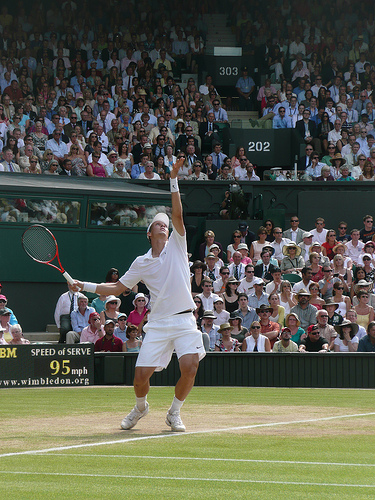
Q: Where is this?
A: This is at the stadium.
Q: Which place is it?
A: It is a stadium.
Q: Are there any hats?
A: Yes, there is a hat.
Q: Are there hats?
A: Yes, there is a hat.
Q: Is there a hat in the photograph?
A: Yes, there is a hat.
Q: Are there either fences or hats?
A: Yes, there is a hat.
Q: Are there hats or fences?
A: Yes, there is a hat.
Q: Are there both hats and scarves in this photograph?
A: No, there is a hat but no scarves.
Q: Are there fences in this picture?
A: No, there are no fences.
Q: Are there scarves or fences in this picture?
A: No, there are no fences or scarves.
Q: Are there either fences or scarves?
A: No, there are no fences or scarves.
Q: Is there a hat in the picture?
A: Yes, there is a hat.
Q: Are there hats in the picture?
A: Yes, there is a hat.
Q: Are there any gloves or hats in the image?
A: Yes, there is a hat.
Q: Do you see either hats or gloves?
A: Yes, there is a hat.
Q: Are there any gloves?
A: No, there are no gloves.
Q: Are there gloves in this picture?
A: No, there are no gloves.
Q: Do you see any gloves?
A: No, there are no gloves.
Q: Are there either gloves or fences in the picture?
A: No, there are no gloves or fences.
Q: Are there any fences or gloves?
A: No, there are no gloves or fences.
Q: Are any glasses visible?
A: No, there are no glasses.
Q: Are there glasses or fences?
A: No, there are no glasses or fences.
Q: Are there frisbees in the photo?
A: No, there are no frisbees.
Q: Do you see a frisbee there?
A: No, there are no frisbees.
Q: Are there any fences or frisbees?
A: No, there are no frisbees or fences.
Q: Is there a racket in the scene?
A: Yes, there is a racket.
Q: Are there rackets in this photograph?
A: Yes, there is a racket.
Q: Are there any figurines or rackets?
A: Yes, there is a racket.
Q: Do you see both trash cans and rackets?
A: No, there is a racket but no trash cans.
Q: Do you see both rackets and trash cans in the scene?
A: No, there is a racket but no trash cans.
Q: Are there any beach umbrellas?
A: No, there are no beach umbrellas.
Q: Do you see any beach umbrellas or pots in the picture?
A: No, there are no beach umbrellas or pots.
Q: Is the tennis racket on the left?
A: Yes, the tennis racket is on the left of the image.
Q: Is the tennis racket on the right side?
A: No, the tennis racket is on the left of the image.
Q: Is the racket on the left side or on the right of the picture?
A: The racket is on the left of the image.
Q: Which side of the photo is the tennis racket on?
A: The tennis racket is on the left of the image.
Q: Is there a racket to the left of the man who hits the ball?
A: Yes, there is a racket to the left of the man.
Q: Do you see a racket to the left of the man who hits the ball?
A: Yes, there is a racket to the left of the man.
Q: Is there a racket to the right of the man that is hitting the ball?
A: No, the racket is to the left of the man.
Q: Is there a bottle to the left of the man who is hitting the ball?
A: No, there is a racket to the left of the man.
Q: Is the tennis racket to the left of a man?
A: Yes, the tennis racket is to the left of a man.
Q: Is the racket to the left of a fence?
A: No, the racket is to the left of a man.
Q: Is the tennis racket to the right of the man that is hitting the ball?
A: No, the tennis racket is to the left of the man.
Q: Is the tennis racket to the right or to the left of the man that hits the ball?
A: The tennis racket is to the left of the man.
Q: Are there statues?
A: No, there are no statues.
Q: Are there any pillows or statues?
A: No, there are no statues or pillows.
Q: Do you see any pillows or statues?
A: No, there are no statues or pillows.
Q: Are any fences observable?
A: No, there are no fences.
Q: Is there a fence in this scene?
A: No, there are no fences.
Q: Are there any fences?
A: No, there are no fences.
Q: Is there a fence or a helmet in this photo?
A: No, there are no fences or helmets.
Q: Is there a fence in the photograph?
A: No, there are no fences.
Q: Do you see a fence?
A: No, there are no fences.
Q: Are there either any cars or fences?
A: No, there are no fences or cars.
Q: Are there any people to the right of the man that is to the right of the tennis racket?
A: Yes, there are people to the right of the man.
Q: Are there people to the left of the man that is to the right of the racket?
A: No, the people are to the right of the man.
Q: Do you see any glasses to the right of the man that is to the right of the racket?
A: No, there are people to the right of the man.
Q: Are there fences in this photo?
A: No, there are no fences.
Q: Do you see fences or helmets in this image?
A: No, there are no fences or helmets.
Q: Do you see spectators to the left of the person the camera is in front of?
A: Yes, there are spectators to the left of the person.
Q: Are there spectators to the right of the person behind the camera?
A: No, the spectators are to the left of the person.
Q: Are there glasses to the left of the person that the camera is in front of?
A: No, there are spectators to the left of the person.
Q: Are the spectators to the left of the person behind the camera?
A: Yes, the spectators are to the left of the person.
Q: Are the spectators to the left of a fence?
A: No, the spectators are to the left of the person.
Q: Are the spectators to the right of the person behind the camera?
A: No, the spectators are to the left of the person.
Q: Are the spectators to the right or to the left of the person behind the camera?
A: The spectators are to the left of the person.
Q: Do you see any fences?
A: No, there are no fences.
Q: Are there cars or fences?
A: No, there are no fences or cars.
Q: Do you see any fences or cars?
A: No, there are no fences or cars.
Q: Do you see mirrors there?
A: No, there are no mirrors.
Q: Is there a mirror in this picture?
A: No, there are no mirrors.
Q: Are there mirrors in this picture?
A: No, there are no mirrors.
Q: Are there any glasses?
A: No, there are no glasses.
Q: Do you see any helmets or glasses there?
A: No, there are no glasses or helmets.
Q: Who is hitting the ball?
A: The man is hitting the ball.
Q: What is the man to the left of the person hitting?
A: The man is hitting the ball.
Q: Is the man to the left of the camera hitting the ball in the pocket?
A: Yes, the man is hitting the ball.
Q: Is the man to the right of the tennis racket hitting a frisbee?
A: No, the man is hitting the ball.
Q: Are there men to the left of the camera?
A: Yes, there is a man to the left of the camera.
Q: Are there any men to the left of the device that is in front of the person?
A: Yes, there is a man to the left of the camera.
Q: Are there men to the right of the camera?
A: No, the man is to the left of the camera.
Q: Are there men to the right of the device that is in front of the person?
A: No, the man is to the left of the camera.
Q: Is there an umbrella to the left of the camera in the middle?
A: No, there is a man to the left of the camera.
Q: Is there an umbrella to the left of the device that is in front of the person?
A: No, there is a man to the left of the camera.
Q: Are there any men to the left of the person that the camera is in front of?
A: Yes, there is a man to the left of the person.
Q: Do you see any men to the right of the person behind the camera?
A: No, the man is to the left of the person.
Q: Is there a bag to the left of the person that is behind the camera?
A: No, there is a man to the left of the person.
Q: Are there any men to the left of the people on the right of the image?
A: Yes, there is a man to the left of the people.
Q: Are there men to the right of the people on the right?
A: No, the man is to the left of the people.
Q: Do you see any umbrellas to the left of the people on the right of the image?
A: No, there is a man to the left of the people.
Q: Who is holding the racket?
A: The man is holding the racket.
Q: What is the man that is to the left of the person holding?
A: The man is holding the racket.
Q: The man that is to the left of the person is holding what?
A: The man is holding the racket.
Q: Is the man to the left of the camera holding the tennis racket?
A: Yes, the man is holding the tennis racket.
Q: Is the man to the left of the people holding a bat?
A: No, the man is holding the tennis racket.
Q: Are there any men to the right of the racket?
A: Yes, there is a man to the right of the racket.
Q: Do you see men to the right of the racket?
A: Yes, there is a man to the right of the racket.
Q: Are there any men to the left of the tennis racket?
A: No, the man is to the right of the tennis racket.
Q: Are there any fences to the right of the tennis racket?
A: No, there is a man to the right of the tennis racket.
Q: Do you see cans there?
A: No, there are no cans.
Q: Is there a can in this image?
A: No, there are no cans.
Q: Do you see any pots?
A: No, there are no pots.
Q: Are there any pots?
A: No, there are no pots.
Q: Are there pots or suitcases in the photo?
A: No, there are no pots or suitcases.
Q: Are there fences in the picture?
A: No, there are no fences.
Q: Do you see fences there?
A: No, there are no fences.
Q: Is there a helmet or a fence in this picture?
A: No, there are no fences or helmets.